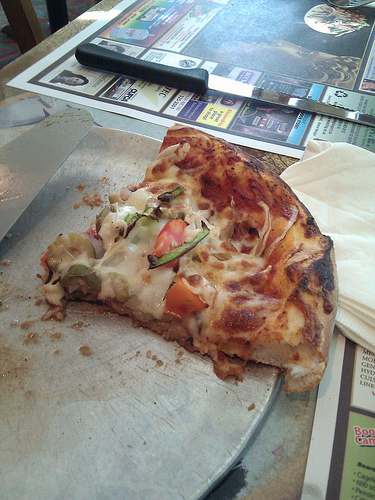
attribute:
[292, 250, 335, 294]
spot — burnt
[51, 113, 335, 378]
pizza — some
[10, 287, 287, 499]
pan — metal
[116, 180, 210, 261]
peppers — green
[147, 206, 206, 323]
tomatoes — some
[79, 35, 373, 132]
knife — one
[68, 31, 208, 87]
handle — black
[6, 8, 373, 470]
table — one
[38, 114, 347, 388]
pizza — thick, crusty, cooked, silver 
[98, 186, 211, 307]
cheese — melted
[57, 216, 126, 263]
onions — red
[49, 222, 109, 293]
olives — green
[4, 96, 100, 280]
server — metal, pizza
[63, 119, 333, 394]
slice — pizza, one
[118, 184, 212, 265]
peppers — green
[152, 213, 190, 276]
tomato — red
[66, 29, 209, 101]
handle — black 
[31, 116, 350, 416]
slice — large 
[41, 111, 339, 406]
cheesy pizza — cheesy 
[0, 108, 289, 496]
silver pan — round 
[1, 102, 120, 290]
silver spatula — silver 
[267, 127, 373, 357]
white napkins — white 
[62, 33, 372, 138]
knife — black handled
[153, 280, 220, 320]
tomato slice — small , red 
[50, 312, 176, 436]
tray — silver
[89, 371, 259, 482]
tray — silver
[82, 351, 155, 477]
tray — silver